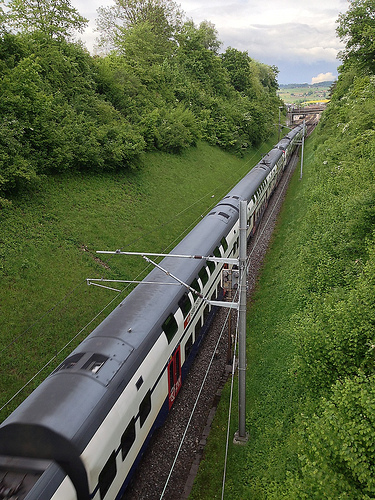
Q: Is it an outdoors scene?
A: Yes, it is outdoors.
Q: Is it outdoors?
A: Yes, it is outdoors.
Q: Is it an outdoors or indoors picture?
A: It is outdoors.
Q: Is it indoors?
A: No, it is outdoors.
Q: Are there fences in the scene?
A: No, there are no fences.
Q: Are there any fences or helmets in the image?
A: No, there are no fences or helmets.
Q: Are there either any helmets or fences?
A: No, there are no fences or helmets.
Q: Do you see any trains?
A: Yes, there is a train.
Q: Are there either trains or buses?
A: Yes, there is a train.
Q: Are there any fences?
A: No, there are no fences.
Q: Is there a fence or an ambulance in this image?
A: No, there are no fences or ambulances.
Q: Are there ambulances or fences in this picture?
A: No, there are no fences or ambulances.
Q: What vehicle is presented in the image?
A: The vehicle is a train.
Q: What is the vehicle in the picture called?
A: The vehicle is a train.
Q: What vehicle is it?
A: The vehicle is a train.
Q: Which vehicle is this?
A: That is a train.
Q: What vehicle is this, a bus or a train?
A: That is a train.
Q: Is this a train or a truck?
A: This is a train.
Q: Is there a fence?
A: No, there are no fences.